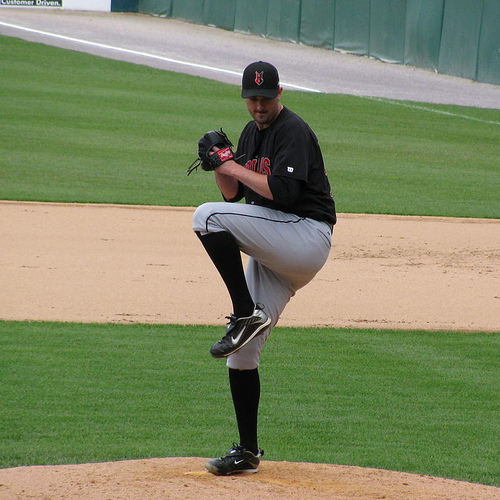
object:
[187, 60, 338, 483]
pitcher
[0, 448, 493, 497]
mound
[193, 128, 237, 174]
glove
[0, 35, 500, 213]
grass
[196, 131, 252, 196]
hand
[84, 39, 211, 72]
line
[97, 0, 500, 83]
wall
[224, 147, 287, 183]
logo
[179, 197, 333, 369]
pants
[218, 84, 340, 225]
jersey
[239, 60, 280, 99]
cap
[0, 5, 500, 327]
ground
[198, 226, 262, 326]
sock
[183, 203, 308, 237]
stripe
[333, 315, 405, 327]
lace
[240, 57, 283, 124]
head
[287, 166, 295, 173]
emblem